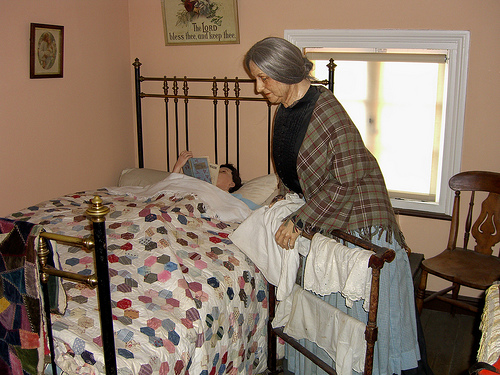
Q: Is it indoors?
A: Yes, it is indoors.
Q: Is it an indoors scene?
A: Yes, it is indoors.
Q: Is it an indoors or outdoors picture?
A: It is indoors.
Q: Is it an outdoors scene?
A: No, it is indoors.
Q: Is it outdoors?
A: No, it is indoors.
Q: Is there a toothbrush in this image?
A: No, there are no toothbrushes.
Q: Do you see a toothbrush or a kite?
A: No, there are no toothbrushes or kites.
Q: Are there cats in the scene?
A: No, there are no cats.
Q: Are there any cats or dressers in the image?
A: No, there are no cats or dressers.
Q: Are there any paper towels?
A: No, there are no paper towels.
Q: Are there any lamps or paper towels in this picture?
A: No, there are no paper towels or lamps.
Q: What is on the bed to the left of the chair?
A: The comforter is on the bed.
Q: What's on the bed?
A: The comforter is on the bed.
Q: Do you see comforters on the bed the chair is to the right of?
A: Yes, there is a comforter on the bed.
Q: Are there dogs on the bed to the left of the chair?
A: No, there is a comforter on the bed.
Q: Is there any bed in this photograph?
A: Yes, there is a bed.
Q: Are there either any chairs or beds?
A: Yes, there is a bed.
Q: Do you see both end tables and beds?
A: No, there is a bed but no end tables.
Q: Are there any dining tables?
A: No, there are no dining tables.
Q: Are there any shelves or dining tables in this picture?
A: No, there are no dining tables or shelves.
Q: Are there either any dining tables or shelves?
A: No, there are no dining tables or shelves.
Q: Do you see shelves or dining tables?
A: No, there are no dining tables or shelves.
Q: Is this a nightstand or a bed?
A: This is a bed.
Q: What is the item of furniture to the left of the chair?
A: The piece of furniture is a bed.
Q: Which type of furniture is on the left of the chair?
A: The piece of furniture is a bed.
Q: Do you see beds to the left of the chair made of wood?
A: Yes, there is a bed to the left of the chair.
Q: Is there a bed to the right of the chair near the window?
A: No, the bed is to the left of the chair.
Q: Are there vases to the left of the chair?
A: No, there is a bed to the left of the chair.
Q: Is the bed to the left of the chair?
A: Yes, the bed is to the left of the chair.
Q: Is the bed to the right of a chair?
A: No, the bed is to the left of a chair.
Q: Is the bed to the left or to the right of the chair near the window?
A: The bed is to the left of the chair.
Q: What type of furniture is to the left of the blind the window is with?
A: The piece of furniture is a bed.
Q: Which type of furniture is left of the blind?
A: The piece of furniture is a bed.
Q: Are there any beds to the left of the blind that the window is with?
A: Yes, there is a bed to the left of the blind.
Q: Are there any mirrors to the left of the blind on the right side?
A: No, there is a bed to the left of the blind.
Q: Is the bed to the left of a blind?
A: Yes, the bed is to the left of a blind.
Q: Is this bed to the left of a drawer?
A: No, the bed is to the left of a blind.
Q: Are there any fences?
A: No, there are no fences.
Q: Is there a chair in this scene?
A: Yes, there is a chair.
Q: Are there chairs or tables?
A: Yes, there is a chair.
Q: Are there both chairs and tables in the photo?
A: No, there is a chair but no tables.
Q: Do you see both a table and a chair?
A: No, there is a chair but no tables.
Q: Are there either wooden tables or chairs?
A: Yes, there is a wood chair.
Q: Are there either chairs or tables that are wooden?
A: Yes, the chair is wooden.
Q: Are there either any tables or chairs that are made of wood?
A: Yes, the chair is made of wood.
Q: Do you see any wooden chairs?
A: Yes, there is a wood chair.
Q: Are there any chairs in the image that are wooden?
A: Yes, there is a wood chair.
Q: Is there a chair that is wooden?
A: Yes, there is a chair that is wooden.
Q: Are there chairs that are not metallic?
A: Yes, there is a wooden chair.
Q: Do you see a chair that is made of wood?
A: Yes, there is a chair that is made of wood.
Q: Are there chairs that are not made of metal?
A: Yes, there is a chair that is made of wood.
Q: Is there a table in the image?
A: No, there are no tables.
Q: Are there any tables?
A: No, there are no tables.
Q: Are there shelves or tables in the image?
A: No, there are no tables or shelves.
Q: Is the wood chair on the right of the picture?
A: Yes, the chair is on the right of the image.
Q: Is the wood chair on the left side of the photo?
A: No, the chair is on the right of the image.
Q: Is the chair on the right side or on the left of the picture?
A: The chair is on the right of the image.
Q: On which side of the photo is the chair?
A: The chair is on the right of the image.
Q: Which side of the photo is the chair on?
A: The chair is on the right of the image.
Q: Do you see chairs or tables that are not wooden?
A: No, there is a chair but it is wooden.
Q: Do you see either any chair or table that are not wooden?
A: No, there is a chair but it is wooden.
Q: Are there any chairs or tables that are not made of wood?
A: No, there is a chair but it is made of wood.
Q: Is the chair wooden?
A: Yes, the chair is wooden.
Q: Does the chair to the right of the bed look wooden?
A: Yes, the chair is wooden.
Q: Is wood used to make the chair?
A: Yes, the chair is made of wood.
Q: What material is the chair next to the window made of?
A: The chair is made of wood.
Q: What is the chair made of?
A: The chair is made of wood.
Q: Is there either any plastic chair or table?
A: No, there is a chair but it is wooden.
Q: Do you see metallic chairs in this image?
A: No, there is a chair but it is wooden.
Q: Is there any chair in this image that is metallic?
A: No, there is a chair but it is wooden.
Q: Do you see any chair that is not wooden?
A: No, there is a chair but it is wooden.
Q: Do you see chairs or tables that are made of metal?
A: No, there is a chair but it is made of wood.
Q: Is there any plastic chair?
A: No, there is a chair but it is made of wood.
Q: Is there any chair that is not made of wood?
A: No, there is a chair but it is made of wood.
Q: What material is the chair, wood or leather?
A: The chair is made of wood.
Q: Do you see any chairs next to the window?
A: Yes, there is a chair next to the window.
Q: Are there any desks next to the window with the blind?
A: No, there is a chair next to the window.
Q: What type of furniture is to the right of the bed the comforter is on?
A: The piece of furniture is a chair.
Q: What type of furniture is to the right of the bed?
A: The piece of furniture is a chair.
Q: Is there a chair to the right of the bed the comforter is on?
A: Yes, there is a chair to the right of the bed.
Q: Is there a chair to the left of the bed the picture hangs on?
A: No, the chair is to the right of the bed.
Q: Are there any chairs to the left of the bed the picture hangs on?
A: No, the chair is to the right of the bed.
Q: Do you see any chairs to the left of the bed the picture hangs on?
A: No, the chair is to the right of the bed.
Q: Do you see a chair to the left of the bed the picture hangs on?
A: No, the chair is to the right of the bed.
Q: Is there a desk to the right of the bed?
A: No, there is a chair to the right of the bed.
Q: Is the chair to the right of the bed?
A: Yes, the chair is to the right of the bed.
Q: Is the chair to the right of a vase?
A: No, the chair is to the right of the bed.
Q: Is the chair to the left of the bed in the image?
A: No, the chair is to the right of the bed.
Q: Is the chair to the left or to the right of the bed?
A: The chair is to the right of the bed.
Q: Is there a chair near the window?
A: Yes, there is a chair near the window.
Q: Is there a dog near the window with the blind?
A: No, there is a chair near the window.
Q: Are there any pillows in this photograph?
A: Yes, there is a pillow.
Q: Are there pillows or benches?
A: Yes, there is a pillow.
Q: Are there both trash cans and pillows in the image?
A: No, there is a pillow but no trash cans.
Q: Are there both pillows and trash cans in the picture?
A: No, there is a pillow but no trash cans.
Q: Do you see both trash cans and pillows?
A: No, there is a pillow but no trash cans.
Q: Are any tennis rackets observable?
A: No, there are no tennis rackets.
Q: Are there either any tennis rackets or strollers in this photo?
A: No, there are no tennis rackets or strollers.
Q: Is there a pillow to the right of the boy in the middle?
A: Yes, there is a pillow to the right of the boy.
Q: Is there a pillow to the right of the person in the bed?
A: Yes, there is a pillow to the right of the boy.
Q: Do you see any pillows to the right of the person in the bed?
A: Yes, there is a pillow to the right of the boy.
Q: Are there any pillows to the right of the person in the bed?
A: Yes, there is a pillow to the right of the boy.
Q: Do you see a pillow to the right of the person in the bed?
A: Yes, there is a pillow to the right of the boy.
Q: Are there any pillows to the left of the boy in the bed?
A: No, the pillow is to the right of the boy.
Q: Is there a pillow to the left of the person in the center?
A: No, the pillow is to the right of the boy.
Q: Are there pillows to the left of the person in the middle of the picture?
A: No, the pillow is to the right of the boy.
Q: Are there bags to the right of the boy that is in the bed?
A: No, there is a pillow to the right of the boy.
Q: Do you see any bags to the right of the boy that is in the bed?
A: No, there is a pillow to the right of the boy.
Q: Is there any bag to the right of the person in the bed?
A: No, there is a pillow to the right of the boy.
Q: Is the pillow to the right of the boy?
A: Yes, the pillow is to the right of the boy.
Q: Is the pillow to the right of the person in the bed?
A: Yes, the pillow is to the right of the boy.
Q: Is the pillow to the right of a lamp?
A: No, the pillow is to the right of the boy.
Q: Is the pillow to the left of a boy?
A: No, the pillow is to the right of a boy.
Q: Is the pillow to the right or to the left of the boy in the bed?
A: The pillow is to the right of the boy.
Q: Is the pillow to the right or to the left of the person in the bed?
A: The pillow is to the right of the boy.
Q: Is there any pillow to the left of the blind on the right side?
A: Yes, there is a pillow to the left of the blind.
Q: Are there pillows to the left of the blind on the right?
A: Yes, there is a pillow to the left of the blind.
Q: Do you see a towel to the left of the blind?
A: No, there is a pillow to the left of the blind.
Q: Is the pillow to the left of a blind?
A: Yes, the pillow is to the left of a blind.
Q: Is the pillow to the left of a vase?
A: No, the pillow is to the left of a blind.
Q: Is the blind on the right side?
A: Yes, the blind is on the right of the image.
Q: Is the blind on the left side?
A: No, the blind is on the right of the image.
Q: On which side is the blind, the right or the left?
A: The blind is on the right of the image.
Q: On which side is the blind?
A: The blind is on the right of the image.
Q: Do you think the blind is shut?
A: Yes, the blind is shut.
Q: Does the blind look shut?
A: Yes, the blind is shut.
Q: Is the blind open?
A: No, the blind is shut.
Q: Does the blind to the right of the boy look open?
A: No, the blind is shut.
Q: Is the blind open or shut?
A: The blind is shut.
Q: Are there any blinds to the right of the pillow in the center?
A: Yes, there is a blind to the right of the pillow.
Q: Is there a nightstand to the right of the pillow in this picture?
A: No, there is a blind to the right of the pillow.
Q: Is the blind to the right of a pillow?
A: Yes, the blind is to the right of a pillow.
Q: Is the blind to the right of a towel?
A: No, the blind is to the right of a pillow.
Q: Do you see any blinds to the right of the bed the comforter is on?
A: Yes, there is a blind to the right of the bed.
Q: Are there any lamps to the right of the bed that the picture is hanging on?
A: No, there is a blind to the right of the bed.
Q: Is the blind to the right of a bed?
A: Yes, the blind is to the right of a bed.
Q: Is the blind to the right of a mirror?
A: No, the blind is to the right of a bed.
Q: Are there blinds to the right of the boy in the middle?
A: Yes, there is a blind to the right of the boy.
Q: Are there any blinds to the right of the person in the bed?
A: Yes, there is a blind to the right of the boy.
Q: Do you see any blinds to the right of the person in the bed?
A: Yes, there is a blind to the right of the boy.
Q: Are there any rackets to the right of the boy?
A: No, there is a blind to the right of the boy.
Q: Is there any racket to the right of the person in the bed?
A: No, there is a blind to the right of the boy.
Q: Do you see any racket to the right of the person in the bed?
A: No, there is a blind to the right of the boy.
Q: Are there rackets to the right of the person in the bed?
A: No, there is a blind to the right of the boy.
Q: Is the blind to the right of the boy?
A: Yes, the blind is to the right of the boy.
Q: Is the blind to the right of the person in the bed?
A: Yes, the blind is to the right of the boy.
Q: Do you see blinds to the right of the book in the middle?
A: Yes, there is a blind to the right of the book.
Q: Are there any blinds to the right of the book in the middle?
A: Yes, there is a blind to the right of the book.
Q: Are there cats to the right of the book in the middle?
A: No, there is a blind to the right of the book.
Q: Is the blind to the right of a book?
A: Yes, the blind is to the right of a book.